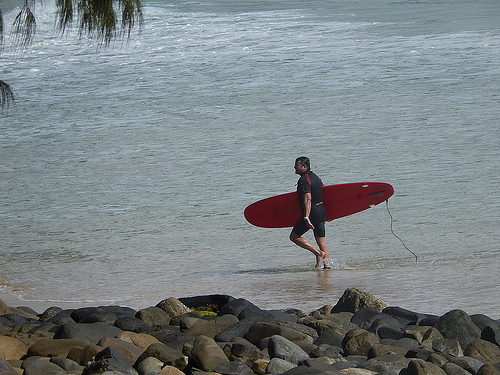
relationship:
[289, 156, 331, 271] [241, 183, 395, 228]
male holding board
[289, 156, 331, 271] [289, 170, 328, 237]
male has wetsuit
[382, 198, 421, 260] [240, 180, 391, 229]
cable on board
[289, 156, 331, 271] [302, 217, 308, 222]
male has watch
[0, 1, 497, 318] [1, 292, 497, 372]
ocean water near shore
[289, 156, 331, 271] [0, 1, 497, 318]
male walking in ocean water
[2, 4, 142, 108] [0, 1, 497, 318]
greenery hanging over ocean water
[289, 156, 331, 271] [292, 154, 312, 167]
male with hair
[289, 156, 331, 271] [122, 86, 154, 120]
male in ocean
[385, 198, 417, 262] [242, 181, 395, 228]
leash on board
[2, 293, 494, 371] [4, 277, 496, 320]
rocks on shore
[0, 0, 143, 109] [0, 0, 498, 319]
greenery overhanging water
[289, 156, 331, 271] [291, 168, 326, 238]
male wearing wetsuit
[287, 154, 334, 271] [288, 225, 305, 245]
male bending knee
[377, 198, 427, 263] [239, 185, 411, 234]
leash on surfboard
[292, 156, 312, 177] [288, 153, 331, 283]
head of a man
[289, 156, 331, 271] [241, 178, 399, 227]
male walking with surfboard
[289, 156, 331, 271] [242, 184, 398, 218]
male holding surfboard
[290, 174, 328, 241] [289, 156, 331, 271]
wetsuit on male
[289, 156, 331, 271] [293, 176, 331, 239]
male wearing wetsuit